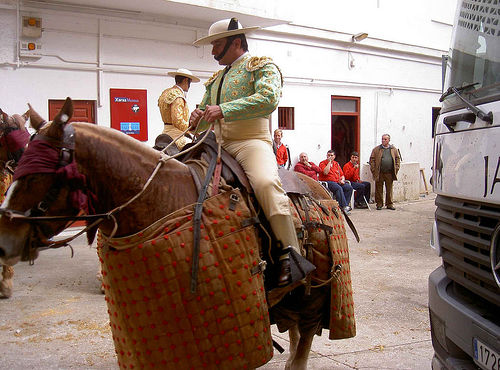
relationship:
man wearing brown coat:
[369, 132, 403, 212] [367, 141, 404, 181]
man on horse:
[369, 132, 403, 212] [11, 106, 363, 360]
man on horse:
[186, 16, 311, 287] [25, 120, 357, 364]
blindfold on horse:
[12, 136, 96, 191] [7, 95, 237, 285]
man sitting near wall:
[369, 132, 403, 212] [115, 2, 469, 210]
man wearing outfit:
[369, 132, 403, 212] [193, 55, 303, 253]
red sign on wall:
[105, 85, 152, 142] [4, 7, 447, 241]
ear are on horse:
[26, 101, 46, 130] [11, 106, 363, 360]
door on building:
[323, 90, 369, 188] [55, 1, 427, 180]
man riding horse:
[186, 16, 311, 287] [31, 114, 340, 344]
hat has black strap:
[191, 16, 264, 48] [215, 13, 240, 70]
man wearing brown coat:
[369, 132, 403, 212] [360, 145, 408, 166]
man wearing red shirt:
[369, 132, 403, 212] [339, 160, 366, 188]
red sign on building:
[105, 85, 151, 138] [0, 0, 448, 212]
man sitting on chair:
[369, 132, 403, 212] [308, 175, 368, 218]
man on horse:
[186, 16, 311, 287] [11, 106, 363, 360]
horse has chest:
[11, 106, 363, 360] [94, 170, 274, 340]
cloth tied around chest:
[104, 196, 275, 353] [94, 170, 274, 340]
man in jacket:
[155, 66, 203, 153] [151, 70, 197, 154]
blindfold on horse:
[11, 139, 101, 210] [11, 106, 363, 360]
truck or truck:
[434, 4, 486, 350] [426, 0, 500, 369]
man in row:
[369, 132, 403, 212] [270, 124, 414, 205]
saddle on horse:
[185, 131, 313, 202] [0, 96, 342, 368]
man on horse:
[369, 132, 403, 212] [0, 96, 342, 368]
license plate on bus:
[460, 334, 494, 366] [412, 2, 496, 367]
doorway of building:
[328, 92, 364, 165] [0, 0, 448, 212]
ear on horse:
[46, 94, 78, 140] [0, 96, 342, 368]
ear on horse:
[26, 101, 46, 130] [0, 96, 342, 368]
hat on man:
[188, 16, 263, 52] [369, 132, 403, 212]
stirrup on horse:
[266, 232, 319, 297] [0, 96, 342, 368]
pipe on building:
[90, 19, 107, 111] [0, 0, 448, 212]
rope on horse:
[94, 109, 218, 226] [0, 96, 342, 368]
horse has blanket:
[11, 106, 363, 360] [92, 192, 356, 368]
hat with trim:
[191, 16, 264, 48] [225, 18, 239, 33]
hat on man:
[191, 16, 264, 48] [186, 16, 311, 287]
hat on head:
[191, 16, 264, 48] [204, 18, 264, 67]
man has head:
[186, 16, 311, 287] [204, 18, 264, 67]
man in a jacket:
[369, 132, 399, 210] [369, 144, 399, 180]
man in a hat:
[192, 14, 302, 284] [191, 17, 261, 47]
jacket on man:
[192, 52, 282, 132] [369, 132, 403, 212]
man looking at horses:
[369, 132, 403, 212] [0, 95, 353, 368]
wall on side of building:
[0, 62, 443, 192] [0, 0, 448, 212]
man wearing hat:
[369, 132, 403, 212] [192, 14, 260, 50]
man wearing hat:
[155, 64, 201, 146] [163, 64, 204, 84]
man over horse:
[369, 132, 403, 212] [3, 118, 343, 368]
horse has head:
[0, 96, 342, 368] [2, 97, 93, 270]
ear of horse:
[46, 95, 79, 140] [0, 96, 342, 368]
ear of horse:
[16, 98, 46, 130] [11, 106, 363, 360]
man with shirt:
[369, 132, 403, 212] [376, 144, 396, 181]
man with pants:
[369, 132, 403, 212] [370, 169, 398, 209]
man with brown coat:
[369, 132, 403, 212] [367, 141, 404, 181]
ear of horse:
[26, 101, 46, 130] [0, 96, 342, 368]